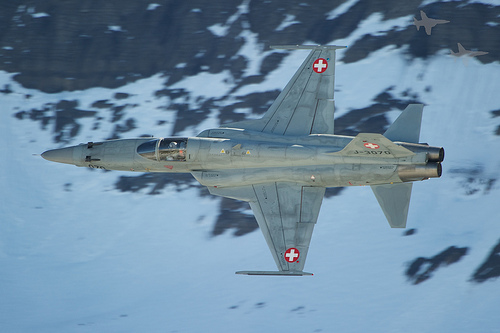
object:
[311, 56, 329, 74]
cross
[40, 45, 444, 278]
plane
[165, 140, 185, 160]
person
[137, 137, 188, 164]
cockpit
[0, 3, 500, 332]
snow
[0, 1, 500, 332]
ground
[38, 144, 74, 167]
nose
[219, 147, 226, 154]
triangle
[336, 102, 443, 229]
tail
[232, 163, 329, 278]
left wing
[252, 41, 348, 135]
right wing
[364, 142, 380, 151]
cross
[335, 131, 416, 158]
vertical stabilizer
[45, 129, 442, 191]
body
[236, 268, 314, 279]
edge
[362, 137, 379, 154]
logo